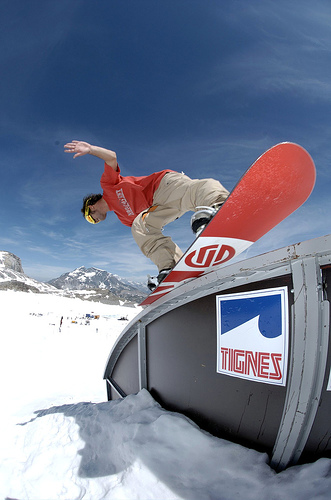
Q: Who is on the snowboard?
A: A man with orange shirt.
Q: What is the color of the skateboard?
A: Red and white.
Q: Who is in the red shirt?
A: A man.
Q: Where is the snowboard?
A: On a ramp.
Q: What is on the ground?
A: Snow.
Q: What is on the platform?
A: Snow.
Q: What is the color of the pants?
A: Beige.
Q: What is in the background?
A: Mountains.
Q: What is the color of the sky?
A: Blue.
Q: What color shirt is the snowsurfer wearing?
A: Red.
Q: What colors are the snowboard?
A: Red and white.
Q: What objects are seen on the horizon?
A: Mountains.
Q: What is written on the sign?
A: TIGNES.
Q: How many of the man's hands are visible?
A: One.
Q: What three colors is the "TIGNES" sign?
A: Red, white, and blue.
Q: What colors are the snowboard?
A: Orange and white.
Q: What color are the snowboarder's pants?
A: Beige.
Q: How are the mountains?
A: Covered with snow.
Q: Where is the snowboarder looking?
A: Down.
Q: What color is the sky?
A: Deep blue.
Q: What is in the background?
A: Mountain peaks.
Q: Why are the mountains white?
A: Snow.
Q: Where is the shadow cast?
A: On the snow.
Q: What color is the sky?
A: Blue.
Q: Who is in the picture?
A: A snowboarder.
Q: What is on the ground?
A: Snow.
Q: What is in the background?
A: Mountains.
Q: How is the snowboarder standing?
A: Balancing.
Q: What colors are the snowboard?
A: Red and white.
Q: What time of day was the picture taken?
A: Daytime.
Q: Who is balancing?
A: The snowboarder.